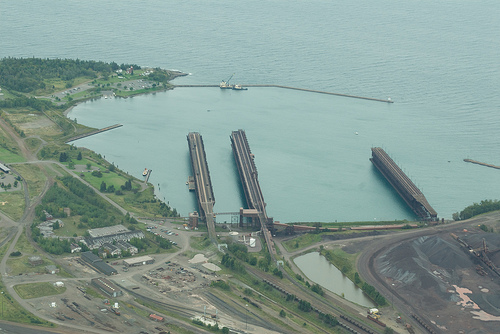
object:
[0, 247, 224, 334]
ground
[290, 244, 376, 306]
water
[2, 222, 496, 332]
land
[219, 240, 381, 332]
road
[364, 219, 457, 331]
road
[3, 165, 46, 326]
road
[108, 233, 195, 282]
road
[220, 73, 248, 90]
boat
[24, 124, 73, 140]
land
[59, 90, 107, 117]
shore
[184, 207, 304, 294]
roadways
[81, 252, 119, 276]
blackroof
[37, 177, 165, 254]
trees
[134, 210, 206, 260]
lot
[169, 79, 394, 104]
runway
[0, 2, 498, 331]
picture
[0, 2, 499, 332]
outdoors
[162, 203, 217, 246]
tower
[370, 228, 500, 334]
quarry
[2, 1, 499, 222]
water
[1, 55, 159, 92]
forest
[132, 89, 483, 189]
water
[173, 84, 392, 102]
barrier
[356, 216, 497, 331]
tarmac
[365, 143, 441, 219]
dock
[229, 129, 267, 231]
dock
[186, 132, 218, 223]
dock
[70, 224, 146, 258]
building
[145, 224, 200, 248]
cars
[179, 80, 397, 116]
station